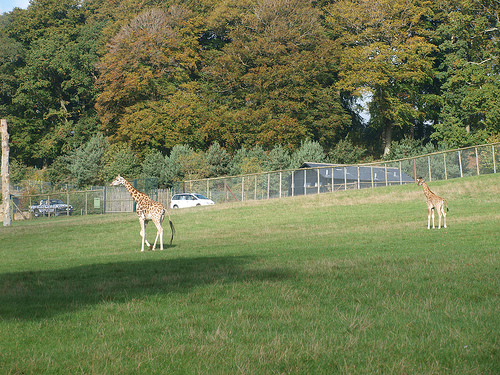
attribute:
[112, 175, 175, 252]
giraffe — larger, brown, white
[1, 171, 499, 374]
field — made up of grass, mostly green, short, dark green, covering ground, grassy, green, yellow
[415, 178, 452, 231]
giraffe — smaller, brown, white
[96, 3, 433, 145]
leaves — slightly yellow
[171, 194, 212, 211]
car — on road, white, parked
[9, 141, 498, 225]
fence — chain link, in background, metal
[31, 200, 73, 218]
truck — black, in background, white, parked, gray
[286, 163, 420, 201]
building — in background, black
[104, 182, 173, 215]
fence gates — wooden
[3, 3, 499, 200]
trees — on hill, leafy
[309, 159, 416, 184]
roof — metal